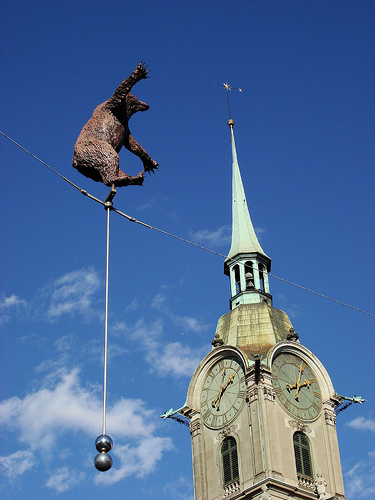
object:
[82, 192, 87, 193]
wire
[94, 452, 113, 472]
ball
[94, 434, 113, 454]
ball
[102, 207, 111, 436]
rod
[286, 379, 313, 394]
hands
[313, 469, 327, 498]
statue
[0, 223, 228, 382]
clouds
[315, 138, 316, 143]
air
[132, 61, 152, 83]
bear paw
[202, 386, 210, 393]
numerals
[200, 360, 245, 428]
face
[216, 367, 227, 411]
hands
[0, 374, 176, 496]
clouds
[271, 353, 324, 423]
clock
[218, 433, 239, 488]
window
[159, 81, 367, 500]
building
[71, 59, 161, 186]
bear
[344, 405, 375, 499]
clouds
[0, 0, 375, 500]
sky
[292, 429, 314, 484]
windows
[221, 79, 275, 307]
steeple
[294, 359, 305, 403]
hands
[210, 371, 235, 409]
hands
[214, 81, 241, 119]
cross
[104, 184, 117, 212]
base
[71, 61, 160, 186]
bear statue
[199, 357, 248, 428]
clock